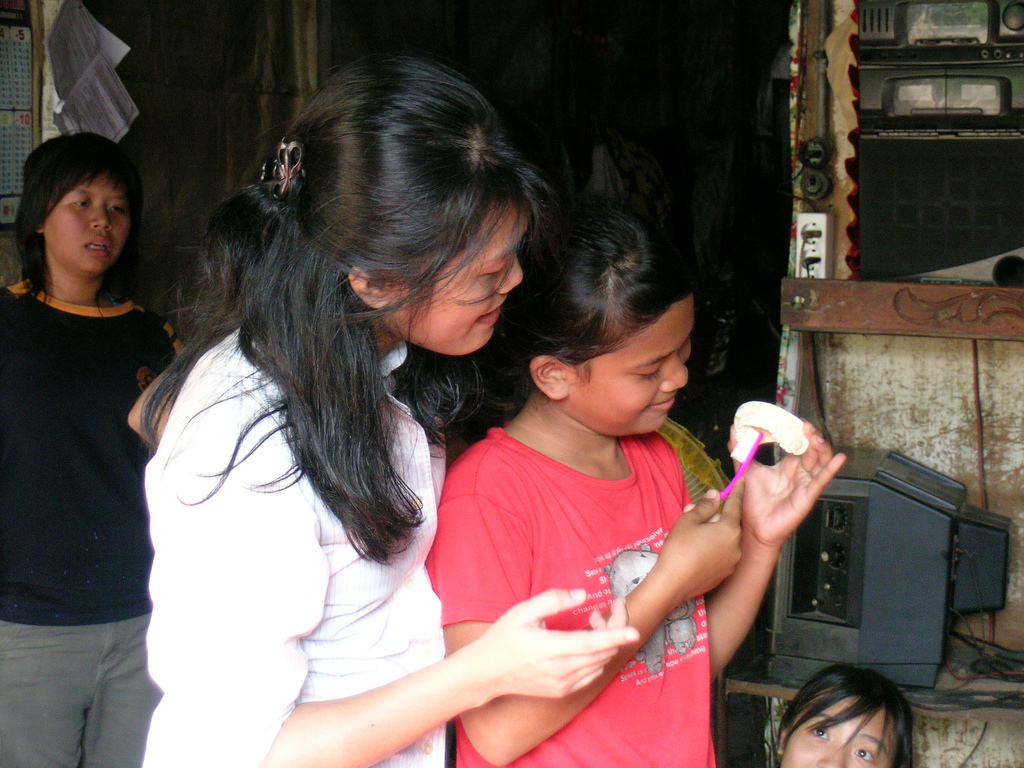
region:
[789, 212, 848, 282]
White electrical outlet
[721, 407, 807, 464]
white object in girl's hand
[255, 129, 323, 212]
a clip in her hair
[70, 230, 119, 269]
a partially open mouth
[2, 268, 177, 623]
black shirt with yellow trim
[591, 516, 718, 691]
a bear on a shirt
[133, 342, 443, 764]
a white shirt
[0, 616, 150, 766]
gray pants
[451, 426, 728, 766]
a pinkish red shirt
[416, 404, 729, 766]
red shirt with cartoon figures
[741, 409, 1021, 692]
old fashion tube television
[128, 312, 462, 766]
white woman's blouse with stripes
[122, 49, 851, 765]
woman teaching child dental hygiene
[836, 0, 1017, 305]
karaoke machine with double sided cassette player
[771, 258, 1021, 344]
wooden shelf hanging on wall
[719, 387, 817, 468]
model denture teaching aide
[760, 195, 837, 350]
power strip hanging on wall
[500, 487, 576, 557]
a shirt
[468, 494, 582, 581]
the shirt is red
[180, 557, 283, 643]
a white sweater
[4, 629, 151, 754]
women is wearing pants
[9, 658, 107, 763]
pants are grey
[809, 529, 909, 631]
the television is black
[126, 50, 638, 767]
woman wearing a white sweater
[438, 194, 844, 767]
child wearing a pink shirt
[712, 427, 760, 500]
pink toothbrush with white bristles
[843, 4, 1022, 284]
old, black stereo system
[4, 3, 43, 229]
wall calendar with blue background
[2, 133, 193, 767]
woman wearing black shirt and gray pants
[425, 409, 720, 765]
pink shirt with a gray logo on the front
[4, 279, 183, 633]
black shirt with gold accents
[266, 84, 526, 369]
head of a woman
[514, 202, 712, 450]
head of a girl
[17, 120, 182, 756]
woman wearing black shirt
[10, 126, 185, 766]
woman wearing gray pants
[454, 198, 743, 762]
child wearing a pink shirt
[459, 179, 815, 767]
child holding false teeth and a toothbrush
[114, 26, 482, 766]
woman wearing a white shirt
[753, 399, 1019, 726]
old television with dust on it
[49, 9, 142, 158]
white papers hanging on wall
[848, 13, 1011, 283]
cassette player with speakers on the bottom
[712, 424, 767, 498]
A pink tooth brush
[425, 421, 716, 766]
A pink tee shirt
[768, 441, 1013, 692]
A black television set.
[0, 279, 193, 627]
A black sweater.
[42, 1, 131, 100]
A white peice of paper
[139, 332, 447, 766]
A white shirt on a woman.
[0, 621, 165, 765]
A gray pair of pants.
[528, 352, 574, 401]
right ear of a child.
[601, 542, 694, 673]
A bear on a shirt.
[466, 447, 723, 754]
the shirt is red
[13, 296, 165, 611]
the sweater is black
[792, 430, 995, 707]
the box is gray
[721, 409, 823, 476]
the girl is holding teeth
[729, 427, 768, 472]
bristles are on the brush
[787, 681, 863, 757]
the girl is looking up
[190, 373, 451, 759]
the shirt is white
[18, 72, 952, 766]
Asian girls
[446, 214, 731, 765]
A girl wearing a red top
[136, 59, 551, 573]
the hair is black